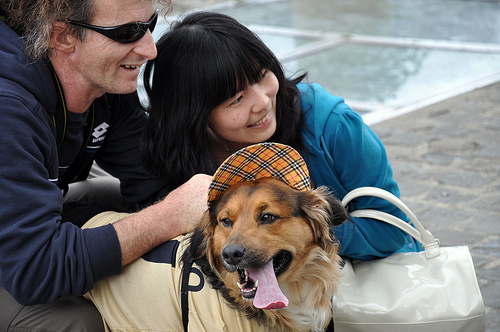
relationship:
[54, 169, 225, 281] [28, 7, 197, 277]
arm of person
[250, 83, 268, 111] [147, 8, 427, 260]
nose of woman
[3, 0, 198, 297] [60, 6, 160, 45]
man wears sun glasses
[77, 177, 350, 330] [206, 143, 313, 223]
dog wearing hat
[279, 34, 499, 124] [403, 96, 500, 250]
window on flooring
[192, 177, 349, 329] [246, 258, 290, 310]
dog sticking out tongue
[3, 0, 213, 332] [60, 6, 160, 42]
man wearing sun glasses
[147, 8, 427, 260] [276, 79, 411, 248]
woman wearing sweater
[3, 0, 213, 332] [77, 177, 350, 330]
man posing with dog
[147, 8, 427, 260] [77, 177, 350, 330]
woman posing with dog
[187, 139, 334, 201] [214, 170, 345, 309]
hat on dog's head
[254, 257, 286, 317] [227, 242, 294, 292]
tongue sticking out of mouth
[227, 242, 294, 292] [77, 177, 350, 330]
mouth of dog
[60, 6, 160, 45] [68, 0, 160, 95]
sun glasses on face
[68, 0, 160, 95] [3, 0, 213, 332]
face of man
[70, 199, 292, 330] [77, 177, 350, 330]
clothes on dog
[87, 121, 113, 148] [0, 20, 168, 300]
logo on man's shirt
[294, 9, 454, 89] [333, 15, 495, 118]
reflections on surface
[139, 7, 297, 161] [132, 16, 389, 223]
head of person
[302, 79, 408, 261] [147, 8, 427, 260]
arm of woman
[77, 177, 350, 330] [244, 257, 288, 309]
dog has tongue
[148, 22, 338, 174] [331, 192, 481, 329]
woman with purse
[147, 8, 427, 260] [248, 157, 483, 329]
woman with purse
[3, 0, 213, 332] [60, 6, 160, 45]
man with sun glasses